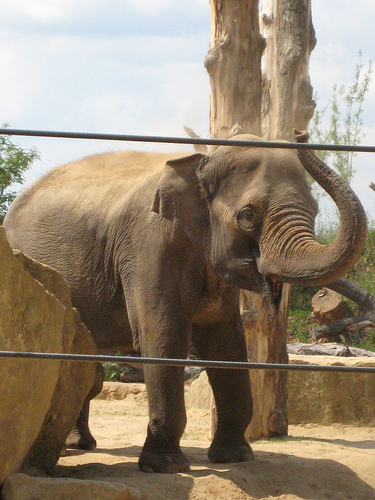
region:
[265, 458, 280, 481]
part of a surface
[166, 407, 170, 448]
leg of an elephant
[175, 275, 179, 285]
leg of an elephant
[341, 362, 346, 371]
edge of a wall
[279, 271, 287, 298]
part of a trunk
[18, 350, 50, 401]
edge of a rock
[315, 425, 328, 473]
part of a surface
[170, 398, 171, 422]
leg of an elephant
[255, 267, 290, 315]
The elephant mouth.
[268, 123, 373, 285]
The rtunk of the elephant.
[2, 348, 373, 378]
The fence wire.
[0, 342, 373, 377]
The wire is grey.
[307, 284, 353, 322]
A stump on the ground.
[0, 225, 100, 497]
A rock by the fence.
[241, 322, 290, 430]
A tree behind the elephant.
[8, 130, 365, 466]
A grey elephant.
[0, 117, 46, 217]
Tree leaves in the corner.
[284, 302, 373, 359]
Trees fallen to the ground.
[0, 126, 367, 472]
a large brown elephant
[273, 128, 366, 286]
elephants truck curled up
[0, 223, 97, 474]
a large tan rock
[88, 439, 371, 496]
shadow from the elephant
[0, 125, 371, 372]
black two wire fence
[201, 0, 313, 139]
two bark-less trees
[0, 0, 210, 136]
cloudy and blue sky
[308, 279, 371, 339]
two different colored logs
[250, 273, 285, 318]
an open elephant's mouth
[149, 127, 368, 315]
happy looking elephant expression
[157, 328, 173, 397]
part of an elephant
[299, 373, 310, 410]
edge of a rock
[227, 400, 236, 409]
leg of an elephant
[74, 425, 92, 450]
part of a surface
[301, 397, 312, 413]
part of a fence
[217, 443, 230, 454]
edge of a toe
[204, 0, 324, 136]
two barren tree trunks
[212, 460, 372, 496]
an elephant's shadow on the ground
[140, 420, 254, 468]
a gray elephant's two front feet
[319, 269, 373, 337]
gray tree branches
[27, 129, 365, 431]
a large gray african elephant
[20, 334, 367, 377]
a metal bar across an enclosure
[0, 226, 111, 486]
a large tan boulder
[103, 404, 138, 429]
tiny patches of grass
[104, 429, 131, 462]
a brown dirt floor in an enclosure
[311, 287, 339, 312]
the flat end of a brown log